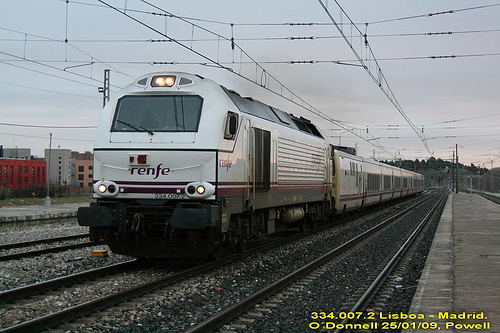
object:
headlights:
[153, 77, 165, 87]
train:
[76, 70, 426, 261]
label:
[126, 162, 172, 180]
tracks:
[0, 233, 105, 263]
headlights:
[195, 184, 205, 195]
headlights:
[96, 183, 109, 193]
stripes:
[216, 184, 255, 189]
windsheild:
[108, 93, 204, 133]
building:
[41, 147, 73, 191]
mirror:
[228, 113, 239, 136]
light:
[447, 173, 453, 176]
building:
[0, 156, 48, 190]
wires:
[0, 26, 66, 42]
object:
[88, 248, 110, 259]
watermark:
[309, 311, 320, 321]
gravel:
[0, 264, 176, 329]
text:
[443, 320, 491, 331]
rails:
[187, 192, 449, 333]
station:
[400, 186, 500, 332]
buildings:
[72, 158, 97, 193]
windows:
[56, 164, 63, 171]